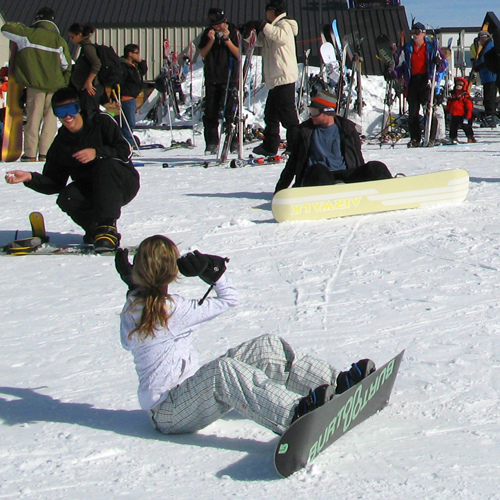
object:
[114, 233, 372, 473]
woman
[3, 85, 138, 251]
man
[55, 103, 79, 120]
goggles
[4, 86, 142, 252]
people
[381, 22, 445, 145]
parent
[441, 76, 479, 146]
child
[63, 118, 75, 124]
smile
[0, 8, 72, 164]
man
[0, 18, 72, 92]
jacket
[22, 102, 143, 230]
gear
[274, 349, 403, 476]
snowboard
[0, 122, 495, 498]
ground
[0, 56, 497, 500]
snow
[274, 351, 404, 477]
board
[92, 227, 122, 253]
boots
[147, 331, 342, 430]
pants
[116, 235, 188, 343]
hair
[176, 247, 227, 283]
gloves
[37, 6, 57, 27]
hat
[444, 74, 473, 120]
coat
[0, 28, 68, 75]
strip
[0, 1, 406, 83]
building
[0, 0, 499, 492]
background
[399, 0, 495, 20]
sky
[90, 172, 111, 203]
black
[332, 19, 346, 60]
ski